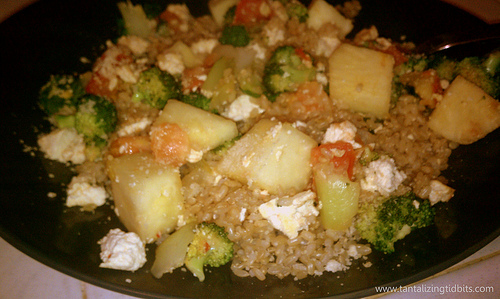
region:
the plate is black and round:
[11, 68, 406, 296]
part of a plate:
[152, 277, 167, 285]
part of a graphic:
[411, 270, 442, 294]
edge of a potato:
[326, 186, 344, 212]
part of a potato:
[254, 137, 294, 183]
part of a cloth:
[31, 277, 57, 293]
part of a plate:
[41, 230, 90, 251]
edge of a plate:
[1, 222, 61, 283]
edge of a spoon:
[431, 41, 463, 53]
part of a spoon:
[462, 28, 484, 53]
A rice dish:
[70, 1, 415, 278]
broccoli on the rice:
[352, 175, 430, 247]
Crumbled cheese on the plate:
[87, 223, 152, 275]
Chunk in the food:
[329, 34, 393, 117]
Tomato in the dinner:
[227, 0, 278, 31]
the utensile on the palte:
[427, 17, 499, 77]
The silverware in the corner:
[407, 7, 497, 58]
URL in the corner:
[367, 277, 492, 297]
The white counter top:
[15, 278, 66, 297]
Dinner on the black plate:
[2, 0, 449, 269]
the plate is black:
[4, 16, 460, 298]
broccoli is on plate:
[38, 62, 144, 170]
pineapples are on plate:
[110, 156, 211, 252]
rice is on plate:
[190, 176, 342, 281]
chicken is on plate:
[239, 94, 396, 221]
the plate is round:
[3, 0, 497, 292]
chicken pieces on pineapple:
[238, 116, 313, 167]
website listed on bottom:
[367, 270, 490, 295]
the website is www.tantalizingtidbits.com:
[365, 280, 495, 295]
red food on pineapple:
[310, 126, 370, 190]